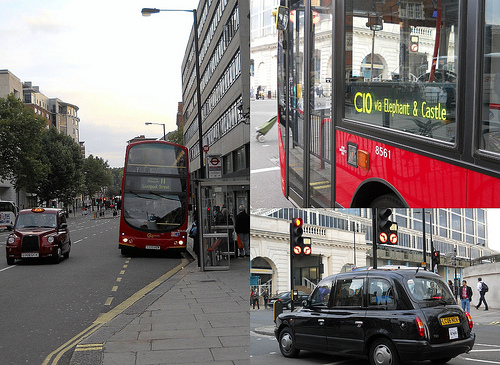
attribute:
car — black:
[276, 270, 473, 361]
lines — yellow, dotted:
[100, 255, 131, 316]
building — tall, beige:
[181, 7, 268, 187]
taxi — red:
[7, 204, 74, 264]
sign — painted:
[342, 77, 451, 131]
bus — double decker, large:
[274, 4, 498, 208]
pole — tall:
[190, 9, 203, 268]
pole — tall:
[158, 124, 168, 143]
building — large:
[248, 209, 367, 305]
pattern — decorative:
[106, 264, 252, 363]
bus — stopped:
[115, 137, 183, 257]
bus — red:
[119, 137, 189, 258]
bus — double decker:
[115, 137, 191, 255]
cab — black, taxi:
[271, 267, 477, 363]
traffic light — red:
[290, 215, 305, 247]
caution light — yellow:
[289, 216, 305, 252]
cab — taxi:
[4, 206, 74, 267]